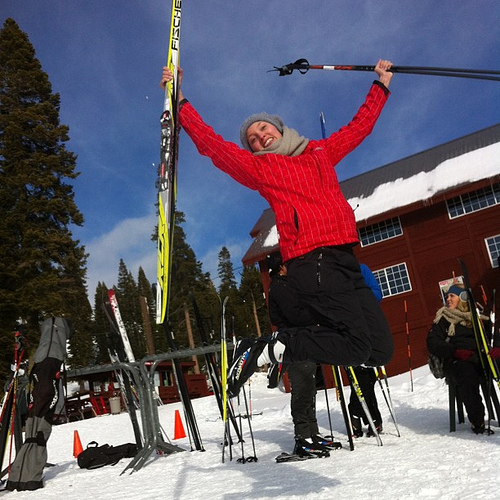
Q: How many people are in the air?
A: One.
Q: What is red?
A: A woman's jacket.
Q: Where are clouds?
A: In the sky.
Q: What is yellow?
A: Skis.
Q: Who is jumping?
A: Skier in red.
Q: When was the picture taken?
A: During the day.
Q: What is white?
A: Snow.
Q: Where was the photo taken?
A: At a ski resort.